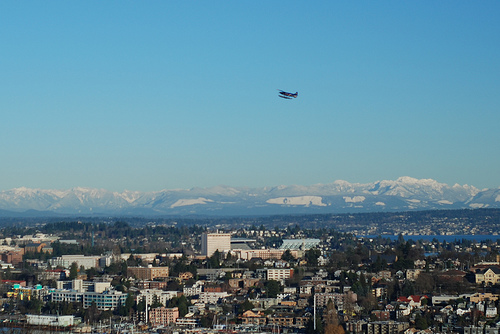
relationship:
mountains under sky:
[0, 175, 500, 218] [3, 6, 494, 172]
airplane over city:
[271, 84, 303, 101] [2, 208, 499, 332]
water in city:
[363, 230, 496, 243] [2, 222, 497, 332]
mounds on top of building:
[8, 276, 72, 300] [6, 287, 46, 297]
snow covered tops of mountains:
[3, 178, 493, 215] [1, 171, 474, 220]